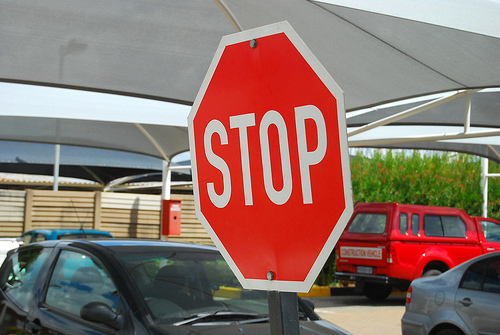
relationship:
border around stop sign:
[185, 21, 353, 294] [187, 20, 355, 292]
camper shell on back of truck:
[337, 200, 478, 244] [334, 201, 499, 301]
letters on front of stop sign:
[202, 104, 329, 210] [187, 20, 355, 292]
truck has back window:
[334, 201, 499, 301] [346, 210, 386, 234]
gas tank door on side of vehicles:
[433, 287, 447, 307] [400, 250, 500, 335]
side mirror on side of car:
[78, 299, 125, 328] [0, 240, 354, 333]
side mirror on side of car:
[299, 297, 316, 315] [0, 240, 354, 333]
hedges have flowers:
[342, 149, 499, 216] [376, 160, 468, 194]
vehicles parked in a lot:
[1, 201, 499, 334] [0, 0, 496, 333]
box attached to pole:
[161, 194, 183, 239] [160, 158, 173, 241]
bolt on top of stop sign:
[247, 38, 257, 49] [187, 20, 355, 292]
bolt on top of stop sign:
[265, 268, 276, 283] [187, 20, 355, 292]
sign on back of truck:
[338, 245, 383, 261] [334, 201, 499, 301]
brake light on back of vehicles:
[402, 285, 413, 304] [400, 250, 500, 335]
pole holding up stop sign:
[265, 290, 302, 334] [187, 20, 355, 292]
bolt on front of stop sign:
[247, 38, 257, 49] [187, 20, 355, 292]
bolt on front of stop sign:
[265, 268, 276, 283] [187, 20, 355, 292]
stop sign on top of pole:
[187, 20, 355, 292] [265, 290, 302, 334]